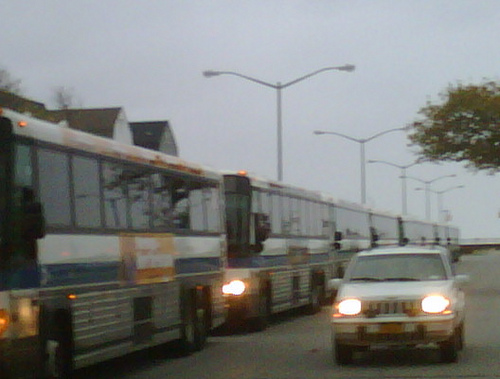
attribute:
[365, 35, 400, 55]
clouds — white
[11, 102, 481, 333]
bus — white and gray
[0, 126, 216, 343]
bus — white, gray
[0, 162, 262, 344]
bus — white, gray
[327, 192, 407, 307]
bus — white, gray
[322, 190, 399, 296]
bus — white, gray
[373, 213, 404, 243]
bus — white, gray, passenger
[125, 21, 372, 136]
clouds — white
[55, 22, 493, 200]
sky — blue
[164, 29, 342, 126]
clouds — white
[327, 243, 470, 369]
car — white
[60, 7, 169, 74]
clouds — white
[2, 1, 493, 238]
sky — blue 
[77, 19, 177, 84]
sky — blue